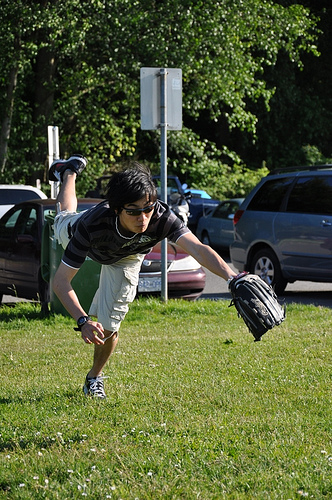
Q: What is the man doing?
A: Diving for the ball.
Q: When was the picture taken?
A: During the day.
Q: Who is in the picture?
A: A man.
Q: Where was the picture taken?
A: In a park.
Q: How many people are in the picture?
A: One.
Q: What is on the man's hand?
A: A baseball glove.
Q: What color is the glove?
A: Black.